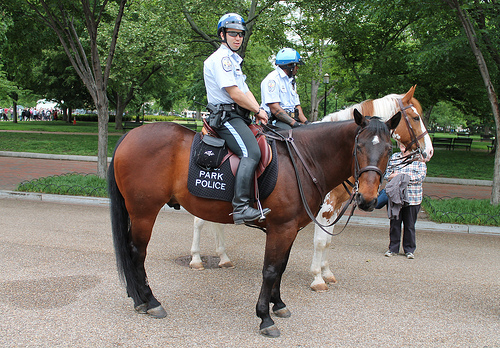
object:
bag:
[198, 134, 226, 171]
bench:
[433, 128, 475, 154]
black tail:
[104, 128, 149, 295]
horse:
[103, 105, 404, 340]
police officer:
[200, 13, 273, 227]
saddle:
[186, 116, 313, 203]